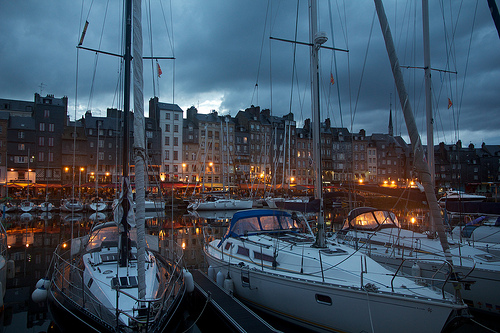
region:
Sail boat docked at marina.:
[67, 199, 119, 321]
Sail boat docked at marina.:
[224, 180, 344, 298]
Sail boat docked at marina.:
[363, 196, 472, 269]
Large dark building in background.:
[7, 93, 87, 151]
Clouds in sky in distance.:
[7, 21, 69, 76]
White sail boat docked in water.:
[195, 185, 248, 231]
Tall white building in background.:
[162, 102, 187, 195]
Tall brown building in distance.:
[349, 132, 366, 184]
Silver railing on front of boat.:
[375, 249, 494, 313]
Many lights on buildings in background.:
[21, 150, 361, 177]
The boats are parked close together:
[10, 21, 490, 319]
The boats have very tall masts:
[5, 12, 496, 315]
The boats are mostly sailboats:
[0, 37, 485, 322]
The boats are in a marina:
[5, 35, 497, 316]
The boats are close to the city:
[17, 63, 494, 326]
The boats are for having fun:
[7, 41, 492, 327]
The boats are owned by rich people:
[5, 32, 492, 317]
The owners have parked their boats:
[3, 35, 490, 318]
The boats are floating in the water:
[6, 27, 491, 325]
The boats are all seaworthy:
[5, 40, 486, 324]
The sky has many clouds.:
[1, 2, 498, 149]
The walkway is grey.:
[147, 262, 305, 332]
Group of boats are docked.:
[0, 182, 498, 331]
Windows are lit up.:
[347, 208, 399, 232]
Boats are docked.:
[1, 2, 498, 331]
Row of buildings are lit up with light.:
[2, 92, 499, 192]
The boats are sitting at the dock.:
[0, 4, 496, 13]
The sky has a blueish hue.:
[2, 2, 499, 148]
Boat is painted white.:
[197, 2, 480, 330]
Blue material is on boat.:
[220, 202, 302, 238]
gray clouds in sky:
[0, 2, 499, 142]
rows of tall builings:
[3, 95, 496, 190]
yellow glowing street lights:
[57, 164, 414, 187]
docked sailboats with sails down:
[48, 3, 492, 330]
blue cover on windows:
[226, 207, 298, 241]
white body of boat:
[206, 235, 469, 330]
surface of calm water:
[3, 208, 437, 330]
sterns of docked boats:
[1, 198, 108, 213]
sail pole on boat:
[311, 0, 323, 245]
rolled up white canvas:
[133, 1, 144, 298]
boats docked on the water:
[9, 187, 284, 213]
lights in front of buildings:
[13, 159, 425, 194]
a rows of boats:
[7, 212, 484, 329]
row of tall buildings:
[8, 94, 470, 201]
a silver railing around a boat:
[40, 243, 194, 328]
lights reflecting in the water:
[33, 214, 220, 260]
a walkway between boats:
[188, 264, 278, 331]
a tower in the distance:
[381, 99, 405, 142]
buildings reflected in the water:
[3, 234, 69, 331]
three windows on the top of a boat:
[226, 213, 308, 233]